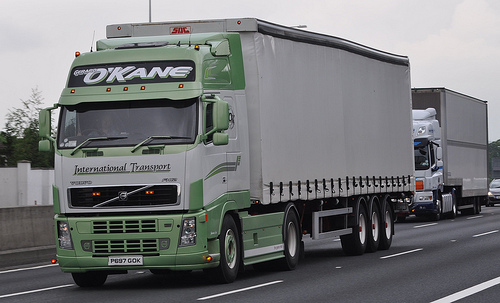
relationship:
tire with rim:
[215, 203, 254, 282] [219, 229, 249, 273]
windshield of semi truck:
[58, 105, 196, 142] [37, 18, 417, 288]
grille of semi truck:
[91, 217, 159, 257] [37, 18, 417, 288]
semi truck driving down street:
[37, 18, 417, 288] [1, 207, 498, 299]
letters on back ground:
[72, 66, 192, 80] [64, 60, 198, 86]